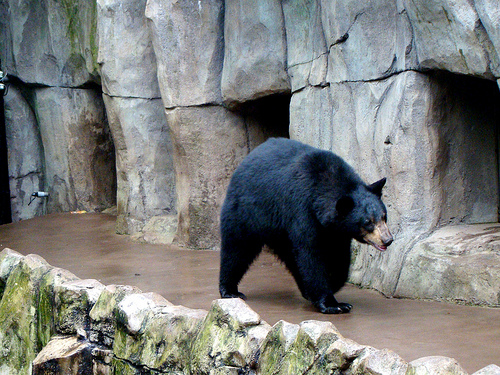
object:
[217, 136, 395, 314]
bear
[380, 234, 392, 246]
nose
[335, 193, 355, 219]
ear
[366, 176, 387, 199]
ear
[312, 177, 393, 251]
head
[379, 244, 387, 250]
tongue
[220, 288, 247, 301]
paw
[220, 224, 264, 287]
leg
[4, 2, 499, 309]
wall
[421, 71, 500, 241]
cave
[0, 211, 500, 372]
pathway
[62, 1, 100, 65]
moss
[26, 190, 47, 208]
camera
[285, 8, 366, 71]
crack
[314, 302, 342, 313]
paw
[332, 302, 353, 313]
paw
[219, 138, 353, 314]
fur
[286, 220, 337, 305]
leg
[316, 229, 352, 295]
leg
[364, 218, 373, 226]
eye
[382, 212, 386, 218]
eye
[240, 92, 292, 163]
opening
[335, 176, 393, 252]
face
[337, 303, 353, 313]
claws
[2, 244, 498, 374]
wall